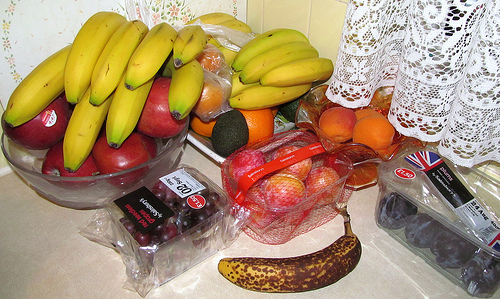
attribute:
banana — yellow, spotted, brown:
[217, 202, 362, 293]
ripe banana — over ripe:
[216, 203, 381, 290]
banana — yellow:
[265, 58, 333, 86]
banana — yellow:
[233, 86, 310, 108]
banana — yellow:
[65, 15, 112, 103]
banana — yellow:
[8, 45, 65, 128]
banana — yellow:
[66, 108, 100, 173]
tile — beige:
[243, 0, 310, 41]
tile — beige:
[307, 0, 349, 45]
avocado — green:
[214, 107, 244, 160]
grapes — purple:
[89, 186, 216, 260]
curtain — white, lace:
[331, 0, 498, 171]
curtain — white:
[305, 40, 498, 116]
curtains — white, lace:
[333, 30, 454, 122]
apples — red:
[20, 85, 181, 174]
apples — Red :
[6, 86, 178, 180]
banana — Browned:
[212, 199, 377, 294]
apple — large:
[16, 106, 78, 148]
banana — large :
[166, 56, 203, 120]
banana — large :
[105, 77, 150, 145]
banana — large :
[6, 45, 72, 130]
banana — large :
[61, 81, 107, 168]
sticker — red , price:
[186, 192, 204, 208]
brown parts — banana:
[275, 258, 358, 275]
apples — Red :
[124, 114, 164, 176]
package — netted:
[221, 127, 355, 245]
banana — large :
[86, 13, 149, 111]